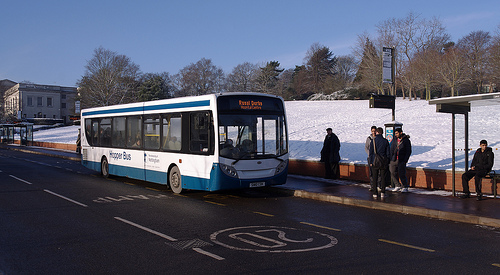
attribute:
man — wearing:
[461, 134, 499, 196]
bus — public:
[19, 44, 335, 245]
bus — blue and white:
[94, 81, 280, 201]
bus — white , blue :
[78, 90, 289, 195]